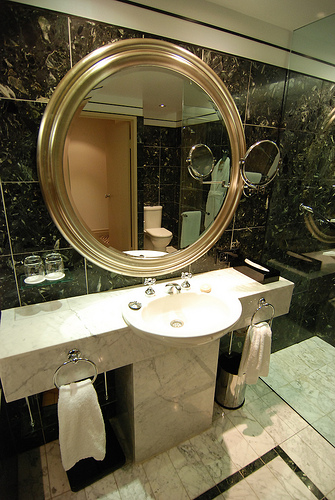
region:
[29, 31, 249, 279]
The mirror is round.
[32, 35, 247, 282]
The mirror has a gold frame.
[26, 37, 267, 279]
The mirror is clean.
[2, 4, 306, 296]
The mirror is hanging on the wall.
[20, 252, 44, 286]
The glass is clear.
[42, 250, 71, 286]
The glass is clear.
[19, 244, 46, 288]
The glass is empty.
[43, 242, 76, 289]
The glass is empty.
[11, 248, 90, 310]
The glasses are on a glass shelf.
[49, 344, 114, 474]
A white towel is hanging on the towel holder.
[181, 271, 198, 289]
faucet on the sink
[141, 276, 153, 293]
faucet on the sink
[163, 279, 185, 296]
nozzle on the sink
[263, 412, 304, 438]
tile on the floor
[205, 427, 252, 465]
tile on the floor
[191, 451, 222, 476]
tile on the floor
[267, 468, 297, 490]
tile on the floor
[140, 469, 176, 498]
tile on the floor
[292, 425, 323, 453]
tile on the floor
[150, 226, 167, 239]
reflection of the toilet.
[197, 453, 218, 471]
marble on the floor.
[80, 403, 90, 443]
towel on the rack.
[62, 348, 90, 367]
rack for the towel.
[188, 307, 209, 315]
basin of the sink.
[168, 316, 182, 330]
drain of the sink.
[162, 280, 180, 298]
faucet on the sink.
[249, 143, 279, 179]
mirror in the bathroom.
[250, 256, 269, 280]
tissues in the box.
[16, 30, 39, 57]
marble on the wall.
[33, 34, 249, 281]
a large wall mirror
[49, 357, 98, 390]
a silver towel ring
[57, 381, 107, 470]
a long white hand towel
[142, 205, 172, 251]
part of a white toilet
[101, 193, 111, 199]
a doorknob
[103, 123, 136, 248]
a bathroom door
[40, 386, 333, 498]
a section of bathroom floor tile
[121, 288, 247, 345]
a large white bathroom sink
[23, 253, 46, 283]
a glass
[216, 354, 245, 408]
a small trashcan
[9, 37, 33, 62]
marble on the wall.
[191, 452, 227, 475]
marble on the floor.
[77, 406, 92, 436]
towel near the sink.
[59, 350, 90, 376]
hanger for the towel.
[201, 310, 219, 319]
basin of the sink.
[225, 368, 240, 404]
trash bin under sink.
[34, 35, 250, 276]
it is a round brown mirror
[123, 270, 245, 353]
the sink is white in color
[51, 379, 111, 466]
a white towel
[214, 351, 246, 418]
a silver trash can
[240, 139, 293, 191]
small mirror